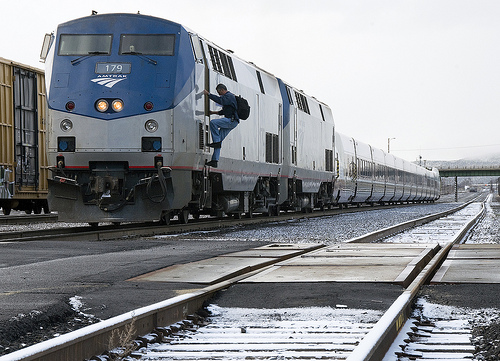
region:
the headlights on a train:
[92, 93, 128, 113]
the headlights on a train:
[53, 115, 72, 132]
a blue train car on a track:
[272, 77, 334, 215]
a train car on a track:
[323, 130, 357, 209]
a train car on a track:
[352, 138, 373, 203]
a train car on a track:
[368, 145, 385, 203]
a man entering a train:
[198, 83, 249, 172]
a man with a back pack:
[200, 81, 251, 167]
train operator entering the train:
[194, 73, 249, 165]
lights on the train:
[93, 98, 123, 111]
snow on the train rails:
[201, 301, 323, 357]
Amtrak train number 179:
[78, 64, 156, 96]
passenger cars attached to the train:
[334, 123, 449, 208]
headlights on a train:
[51, 118, 166, 138]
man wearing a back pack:
[230, 87, 255, 124]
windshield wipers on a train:
[61, 47, 160, 72]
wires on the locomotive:
[44, 154, 172, 211]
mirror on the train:
[39, 6, 59, 67]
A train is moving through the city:
[16, 0, 473, 343]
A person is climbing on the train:
[30, 5, 495, 355]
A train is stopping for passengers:
[20, 7, 475, 343]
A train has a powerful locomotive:
[12, 6, 462, 341]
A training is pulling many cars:
[30, 5, 450, 335]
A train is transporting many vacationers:
[16, 11, 461, 336]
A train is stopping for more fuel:
[15, 5, 485, 346]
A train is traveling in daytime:
[10, 2, 485, 327]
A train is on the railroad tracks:
[18, 6, 459, 307]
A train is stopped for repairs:
[11, 3, 442, 322]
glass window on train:
[56, 29, 113, 54]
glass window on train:
[116, 29, 175, 54]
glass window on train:
[335, 151, 347, 178]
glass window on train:
[344, 153, 354, 175]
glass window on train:
[351, 157, 356, 179]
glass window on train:
[353, 158, 360, 179]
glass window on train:
[361, 161, 368, 183]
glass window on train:
[205, 43, 219, 70]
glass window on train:
[218, 48, 233, 74]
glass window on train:
[256, 67, 266, 93]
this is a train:
[51, 0, 497, 273]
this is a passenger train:
[34, 10, 482, 278]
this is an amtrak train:
[5, 5, 493, 299]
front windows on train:
[40, 8, 182, 87]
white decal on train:
[80, 62, 135, 94]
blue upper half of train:
[51, 16, 198, 127]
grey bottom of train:
[28, 88, 231, 188]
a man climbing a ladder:
[195, 75, 265, 216]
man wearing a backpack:
[218, 81, 268, 129]